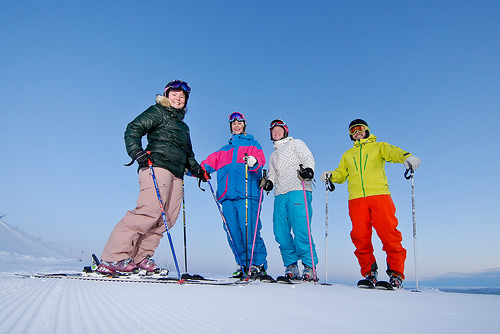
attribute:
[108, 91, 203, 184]
jacket — green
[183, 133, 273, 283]
ski suit — blue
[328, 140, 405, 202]
jacket — yellow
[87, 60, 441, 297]
women — four, skiing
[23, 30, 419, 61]
skies — clear blue 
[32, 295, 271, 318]
snow — white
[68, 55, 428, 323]
women — smiling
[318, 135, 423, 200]
jacket — yellow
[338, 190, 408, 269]
pants — orange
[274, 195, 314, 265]
pants — blue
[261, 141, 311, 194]
jacket — white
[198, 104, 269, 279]
person — pink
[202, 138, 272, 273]
ski outfit — blue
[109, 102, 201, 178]
jacket — dark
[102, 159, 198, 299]
pants — tan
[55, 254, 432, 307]
skies — four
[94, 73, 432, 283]
friends — four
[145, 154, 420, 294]
four sets — ski poles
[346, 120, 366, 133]
ski goggles — yellow and orange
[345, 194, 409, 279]
ski pants — Bright orange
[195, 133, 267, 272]
ski suit — Blue and pink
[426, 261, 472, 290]
mountains — in the distance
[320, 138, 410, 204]
snow coat — yellow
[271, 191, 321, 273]
snow pants — bright blue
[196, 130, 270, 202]
snow jacket — womans, blue, with pink stripe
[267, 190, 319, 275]
snow pants — ladies, bright blue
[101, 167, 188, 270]
snow pants — womans, gray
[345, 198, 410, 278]
snow pants — bright orange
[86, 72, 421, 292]
four skiers — posing, posing together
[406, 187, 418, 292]
ski poles — blue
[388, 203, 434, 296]
ski poles — pink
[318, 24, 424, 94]
sky — blue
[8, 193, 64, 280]
slope — snowy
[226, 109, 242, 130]
ski goggles — blue, pink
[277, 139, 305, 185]
shirt — turtleneck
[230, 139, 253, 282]
jacket ,pants — yellow, red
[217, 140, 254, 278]
ski outfit — matching blue, pink